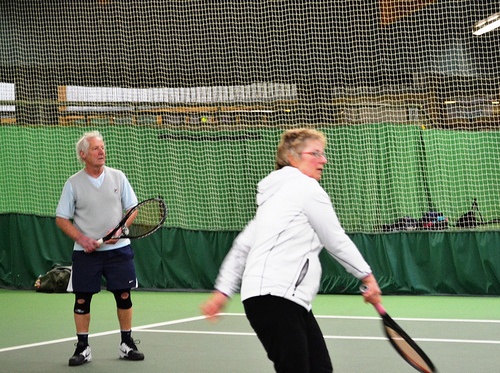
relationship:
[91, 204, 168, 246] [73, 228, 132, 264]
racket in a mans hand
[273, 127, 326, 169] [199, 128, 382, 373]
hair on female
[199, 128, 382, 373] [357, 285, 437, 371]
female holding tennis racket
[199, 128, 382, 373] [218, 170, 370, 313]
female wears jacket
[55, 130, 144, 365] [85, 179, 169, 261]
male holding racket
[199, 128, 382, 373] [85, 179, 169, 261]
female holding racket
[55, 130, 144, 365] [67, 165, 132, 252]
male wears sweater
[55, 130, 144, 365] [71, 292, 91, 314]
male wears knee brace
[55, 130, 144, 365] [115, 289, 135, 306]
male wears knee brace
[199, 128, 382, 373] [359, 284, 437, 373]
female swings racket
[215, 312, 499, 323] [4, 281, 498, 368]
line on tennis court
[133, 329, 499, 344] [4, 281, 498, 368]
line on tennis court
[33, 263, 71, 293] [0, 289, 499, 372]
bag on floor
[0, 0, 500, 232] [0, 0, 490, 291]
green net hanging on wall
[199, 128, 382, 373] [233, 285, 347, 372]
female wears pants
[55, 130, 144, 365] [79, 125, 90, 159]
male has hair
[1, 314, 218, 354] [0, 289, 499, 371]
line on floor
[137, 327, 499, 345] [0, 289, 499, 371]
line on floor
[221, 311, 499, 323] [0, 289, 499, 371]
line on floor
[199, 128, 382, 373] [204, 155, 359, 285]
female wears jacket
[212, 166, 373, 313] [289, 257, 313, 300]
hoodie has pocket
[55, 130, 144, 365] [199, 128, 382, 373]
male with female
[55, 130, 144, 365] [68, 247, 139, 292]
male wears shorts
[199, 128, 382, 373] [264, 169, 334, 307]
female wears hoodie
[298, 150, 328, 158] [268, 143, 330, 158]
eyeglasses over woman's eyes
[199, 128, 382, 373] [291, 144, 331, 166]
female wearing glasses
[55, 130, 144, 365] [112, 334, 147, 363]
male wearing shoe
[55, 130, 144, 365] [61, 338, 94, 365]
male wearing shoe